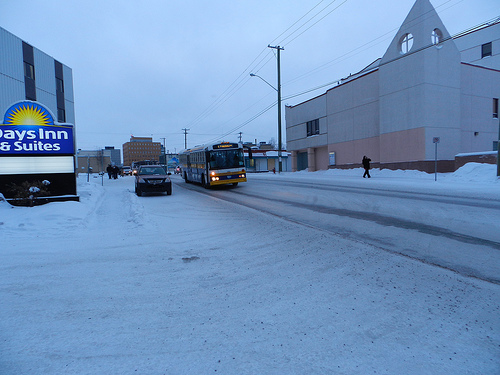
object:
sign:
[0, 99, 77, 177]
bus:
[173, 141, 248, 192]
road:
[0, 178, 499, 375]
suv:
[132, 164, 172, 197]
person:
[360, 155, 372, 179]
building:
[283, 0, 499, 171]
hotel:
[0, 29, 76, 182]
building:
[121, 135, 168, 171]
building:
[73, 149, 111, 173]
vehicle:
[120, 168, 133, 176]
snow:
[0, 161, 499, 374]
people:
[105, 164, 115, 181]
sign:
[430, 138, 438, 146]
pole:
[275, 48, 283, 173]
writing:
[51, 142, 61, 152]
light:
[246, 72, 257, 78]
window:
[406, 32, 414, 54]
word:
[216, 143, 234, 149]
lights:
[210, 178, 213, 182]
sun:
[7, 104, 51, 128]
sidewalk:
[245, 169, 499, 206]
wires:
[279, 0, 454, 88]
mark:
[180, 256, 198, 262]